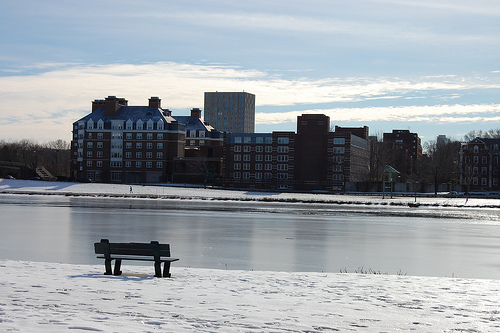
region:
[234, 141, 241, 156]
window of a building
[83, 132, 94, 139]
window of a building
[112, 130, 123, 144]
window of a building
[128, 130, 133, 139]
window of a building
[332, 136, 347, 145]
window of a building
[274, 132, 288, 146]
window of a building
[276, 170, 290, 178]
window of a building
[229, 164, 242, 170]
window of a building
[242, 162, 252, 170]
window of a building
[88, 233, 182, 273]
bench by river looking at city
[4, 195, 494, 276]
still water in winter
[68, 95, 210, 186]
large building across the water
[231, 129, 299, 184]
large building across the water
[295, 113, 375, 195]
large building across the water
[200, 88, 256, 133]
large building across the water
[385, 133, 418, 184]
large building across the water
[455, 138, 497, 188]
large building across the water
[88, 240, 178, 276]
empty black bench by water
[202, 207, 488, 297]
frozen water on a river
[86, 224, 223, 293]
bench near a frozen river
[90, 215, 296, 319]
bench near a frozen body of water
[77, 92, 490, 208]
many dark brick buildigns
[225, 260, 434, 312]
snow on the ground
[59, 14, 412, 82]
white clouds in the sky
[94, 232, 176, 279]
dark wood bench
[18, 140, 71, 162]
trees with no leaves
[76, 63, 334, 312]
SNOW IS ON THE GROUND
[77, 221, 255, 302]
THE BENCH IS MADE OF WOOD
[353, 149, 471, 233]
TREES ARE ON THE GROUND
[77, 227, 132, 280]
THE BENCH STANDS ALONE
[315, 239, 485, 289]
GRASS IS IN THE SNOW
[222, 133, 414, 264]
WINDOWS ARE ON THE BUILDING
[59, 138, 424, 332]
view is at a beach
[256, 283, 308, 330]
floor is covered of sand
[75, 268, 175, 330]
footprints are seen on the sand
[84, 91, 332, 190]
buildigs are adjacent to the sea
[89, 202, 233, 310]
bench is next to the ocean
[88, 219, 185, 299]
the bench is wooden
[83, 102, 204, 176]
building has many windows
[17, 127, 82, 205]
trees are at the background